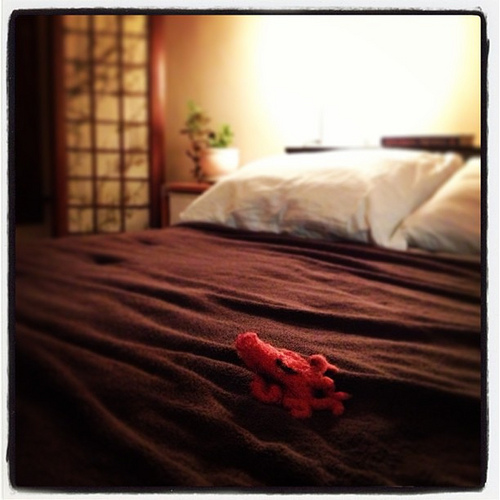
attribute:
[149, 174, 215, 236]
table — small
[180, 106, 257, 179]
plant — small, green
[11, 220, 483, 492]
covers — dark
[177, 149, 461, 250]
pillow — white